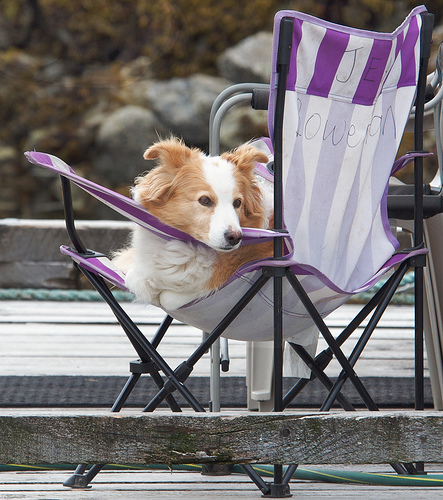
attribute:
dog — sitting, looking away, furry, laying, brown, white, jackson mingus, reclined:
[130, 142, 289, 303]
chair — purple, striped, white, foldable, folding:
[24, 8, 430, 414]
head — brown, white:
[156, 138, 262, 253]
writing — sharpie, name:
[294, 31, 406, 151]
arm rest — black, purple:
[32, 146, 284, 255]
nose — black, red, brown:
[217, 233, 240, 243]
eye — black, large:
[201, 192, 213, 210]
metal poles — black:
[68, 283, 442, 498]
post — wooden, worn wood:
[1, 410, 439, 460]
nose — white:
[214, 192, 240, 253]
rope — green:
[1, 274, 422, 305]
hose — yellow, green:
[2, 460, 439, 484]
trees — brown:
[2, 3, 435, 207]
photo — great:
[4, 2, 439, 499]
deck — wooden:
[4, 276, 440, 497]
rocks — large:
[91, 35, 289, 178]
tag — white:
[281, 335, 319, 379]